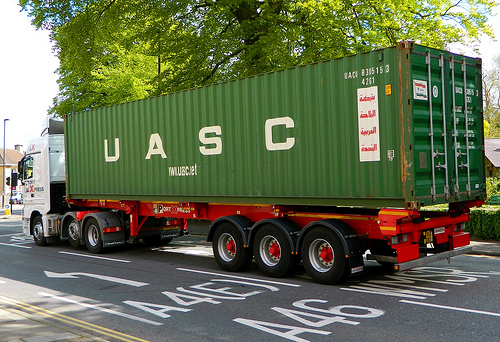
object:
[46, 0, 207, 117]
trees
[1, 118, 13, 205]
lamppost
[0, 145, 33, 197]
building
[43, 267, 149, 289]
white arrow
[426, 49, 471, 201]
bars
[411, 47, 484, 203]
wall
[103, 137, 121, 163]
letter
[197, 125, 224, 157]
letter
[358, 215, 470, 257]
red areas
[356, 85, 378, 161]
sign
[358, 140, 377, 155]
word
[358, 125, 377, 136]
word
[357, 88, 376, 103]
word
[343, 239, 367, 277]
mudflap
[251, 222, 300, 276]
tire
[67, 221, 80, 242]
rim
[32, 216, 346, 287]
black wheels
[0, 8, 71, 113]
sky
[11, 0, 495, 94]
tree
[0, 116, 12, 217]
lamp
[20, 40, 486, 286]
truck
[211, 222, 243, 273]
wheel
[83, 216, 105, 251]
wheel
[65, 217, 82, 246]
wheel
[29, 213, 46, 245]
wheel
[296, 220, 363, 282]
tire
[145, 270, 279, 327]
pavement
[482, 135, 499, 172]
house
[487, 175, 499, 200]
hedges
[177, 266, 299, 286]
line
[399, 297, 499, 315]
line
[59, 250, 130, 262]
line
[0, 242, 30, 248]
line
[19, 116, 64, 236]
cab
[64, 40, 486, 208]
container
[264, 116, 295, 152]
letter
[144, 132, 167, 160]
letter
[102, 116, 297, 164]
name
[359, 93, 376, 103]
name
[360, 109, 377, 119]
name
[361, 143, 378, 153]
name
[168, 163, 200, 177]
name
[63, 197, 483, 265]
bed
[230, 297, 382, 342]
letters/numbers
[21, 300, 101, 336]
lines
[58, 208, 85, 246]
wheel